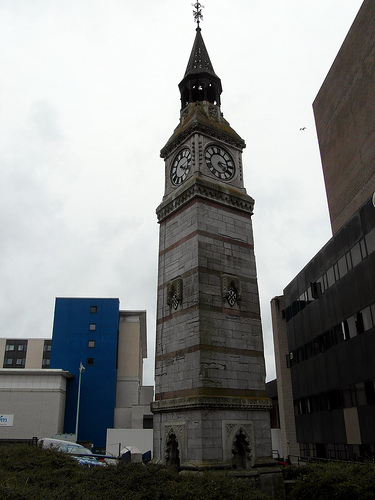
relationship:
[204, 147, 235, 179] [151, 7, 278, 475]
clock on tower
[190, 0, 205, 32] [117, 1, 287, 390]
point on top of tower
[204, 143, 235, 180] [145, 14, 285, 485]
clock on tower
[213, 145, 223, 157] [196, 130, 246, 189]
roman numeral on clock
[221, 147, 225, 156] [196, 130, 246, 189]
roman numeral on clock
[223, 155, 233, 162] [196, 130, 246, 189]
roman numeral on clock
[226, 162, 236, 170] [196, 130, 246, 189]
roman numeral on clock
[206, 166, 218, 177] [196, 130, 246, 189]
roman numeral on clock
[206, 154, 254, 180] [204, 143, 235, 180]
hands on clock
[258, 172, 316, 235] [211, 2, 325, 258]
clouds in sky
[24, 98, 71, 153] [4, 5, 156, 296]
clouds in sky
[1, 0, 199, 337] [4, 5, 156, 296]
clouds in sky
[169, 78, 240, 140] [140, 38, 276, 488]
roof on tower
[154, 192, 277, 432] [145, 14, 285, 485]
wall on tower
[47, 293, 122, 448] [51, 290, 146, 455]
wall on side building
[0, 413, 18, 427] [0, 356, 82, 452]
sign on side building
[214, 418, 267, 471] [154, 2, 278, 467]
archway on side building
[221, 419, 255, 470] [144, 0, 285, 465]
archway on side building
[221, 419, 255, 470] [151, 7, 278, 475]
archway on tower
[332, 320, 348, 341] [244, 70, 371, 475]
window on building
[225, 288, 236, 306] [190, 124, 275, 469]
shield on wall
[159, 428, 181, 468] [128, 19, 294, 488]
archway into tower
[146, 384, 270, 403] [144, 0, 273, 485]
stripe on building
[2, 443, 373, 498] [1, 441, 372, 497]
grass covering ground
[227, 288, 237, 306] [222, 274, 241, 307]
shield on window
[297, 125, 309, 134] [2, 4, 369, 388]
bird in sky